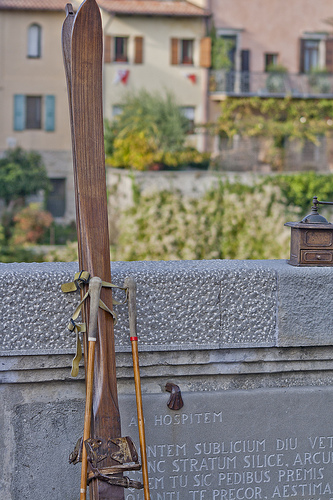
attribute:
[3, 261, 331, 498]
slab — marble, gray, concrete, monument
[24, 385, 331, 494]
letter — gray, roman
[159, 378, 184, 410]
bracket — iron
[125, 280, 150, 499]
handle — grand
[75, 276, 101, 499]
handle — grand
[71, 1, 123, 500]
ski poles — brown, old, antique, standing up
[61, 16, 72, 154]
ski poles — brown, old, antique, standing up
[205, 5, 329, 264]
builduing — old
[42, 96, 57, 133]
shutter — green+, green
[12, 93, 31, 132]
shutter — green+, green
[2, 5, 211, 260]
builduing — old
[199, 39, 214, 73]
shutter — brown, dark brown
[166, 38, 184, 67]
shutter — brown, dark brown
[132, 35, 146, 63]
shutter — brown, dark brown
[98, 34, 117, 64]
shutter — brown, dark brown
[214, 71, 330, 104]
balcony — black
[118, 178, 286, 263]
leaves — green, yellow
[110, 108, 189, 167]
leaves — green, yellow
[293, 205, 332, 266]
grinder — coffe, antique, wooden